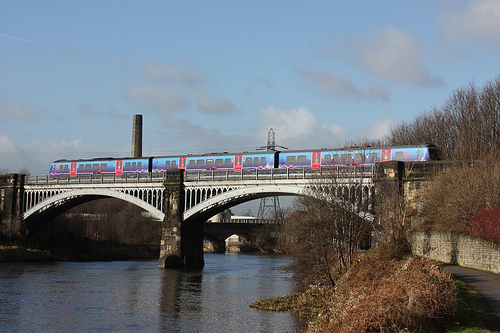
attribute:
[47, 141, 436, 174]
train — red, blue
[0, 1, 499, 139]
sky — huge, clean, clear, big, massive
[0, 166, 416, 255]
bridge — metal, stone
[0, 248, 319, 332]
water — small, brown, blue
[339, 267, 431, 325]
grass — dry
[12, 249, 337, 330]
water — calm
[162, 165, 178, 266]
pillar — stone like 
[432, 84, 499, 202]
branches — dry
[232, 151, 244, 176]
door — closed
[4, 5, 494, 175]
sky — blue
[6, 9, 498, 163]
sky — blue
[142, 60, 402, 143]
clouds — white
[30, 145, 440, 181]
train — long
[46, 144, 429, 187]
train — blue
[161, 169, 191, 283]
column — stone, grey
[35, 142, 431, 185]
train — red, blue